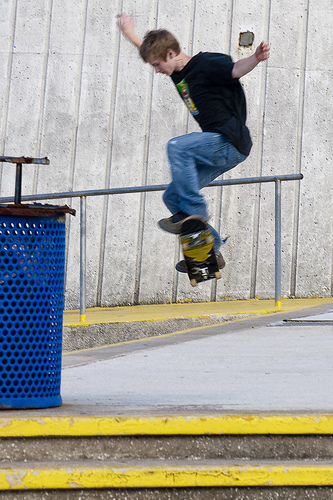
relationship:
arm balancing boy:
[198, 39, 271, 79] [115, 11, 270, 279]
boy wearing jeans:
[115, 11, 270, 279] [161, 130, 248, 254]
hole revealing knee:
[168, 138, 178, 145] [166, 136, 190, 157]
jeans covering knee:
[161, 130, 248, 254] [166, 136, 190, 157]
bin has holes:
[11, 221, 62, 411] [7, 248, 49, 272]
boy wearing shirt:
[119, 26, 274, 337] [183, 52, 261, 149]